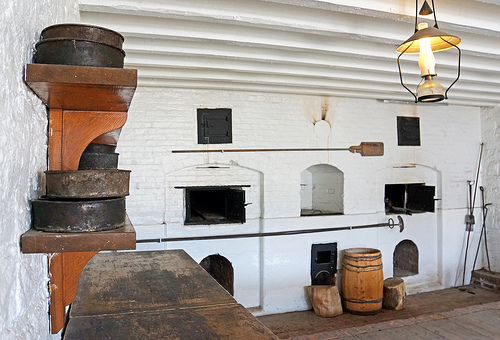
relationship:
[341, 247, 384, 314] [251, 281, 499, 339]
barrel on floor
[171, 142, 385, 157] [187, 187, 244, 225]
tool puts bread in oven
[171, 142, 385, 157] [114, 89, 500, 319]
tool on wall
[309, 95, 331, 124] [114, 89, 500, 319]
burn marks on wall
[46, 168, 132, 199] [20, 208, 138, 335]
pan on shelf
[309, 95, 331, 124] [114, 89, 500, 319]
burn marks are on wall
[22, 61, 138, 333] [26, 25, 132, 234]
shelves with pans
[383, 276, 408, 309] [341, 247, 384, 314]
stump next to barrel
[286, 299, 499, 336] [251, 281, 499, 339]
bricks on floor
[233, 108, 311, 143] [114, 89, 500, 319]
bricks on wall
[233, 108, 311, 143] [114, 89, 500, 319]
bricks are on wall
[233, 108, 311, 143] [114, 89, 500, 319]
bricks in wall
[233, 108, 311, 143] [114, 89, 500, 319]
bricks are part of wall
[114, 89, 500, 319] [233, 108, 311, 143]
wall with bricks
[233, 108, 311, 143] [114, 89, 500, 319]
bricks inside wall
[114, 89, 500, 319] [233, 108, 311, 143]
wall made from bricks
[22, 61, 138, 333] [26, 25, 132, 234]
shelves have pans